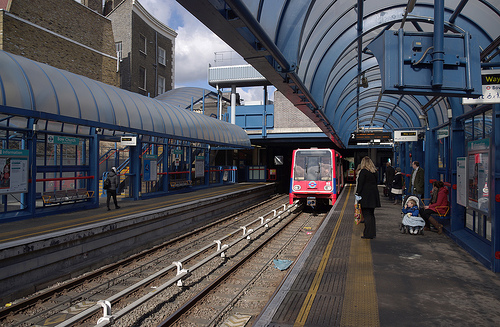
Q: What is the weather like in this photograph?
A: It is cloudy.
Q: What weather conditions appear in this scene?
A: It is cloudy.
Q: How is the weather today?
A: It is cloudy.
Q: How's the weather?
A: It is cloudy.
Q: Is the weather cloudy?
A: Yes, it is cloudy.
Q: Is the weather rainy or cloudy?
A: It is cloudy.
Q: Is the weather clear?
A: No, it is cloudy.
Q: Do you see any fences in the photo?
A: No, there are no fences.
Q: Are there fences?
A: No, there are no fences.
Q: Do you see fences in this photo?
A: No, there are no fences.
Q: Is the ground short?
A: Yes, the ground is short.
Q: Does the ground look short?
A: Yes, the ground is short.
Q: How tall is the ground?
A: The ground is short.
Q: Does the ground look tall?
A: No, the ground is short.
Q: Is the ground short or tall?
A: The ground is short.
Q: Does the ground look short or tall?
A: The ground is short.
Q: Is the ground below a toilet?
A: No, the ground is below the woman.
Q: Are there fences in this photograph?
A: No, there are no fences.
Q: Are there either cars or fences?
A: No, there are no fences or cars.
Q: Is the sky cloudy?
A: Yes, the sky is cloudy.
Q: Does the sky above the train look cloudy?
A: Yes, the sky is cloudy.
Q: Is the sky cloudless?
A: No, the sky is cloudy.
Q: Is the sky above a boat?
A: No, the sky is above a woman.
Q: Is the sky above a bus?
A: No, the sky is above the train.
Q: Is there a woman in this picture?
A: Yes, there is a woman.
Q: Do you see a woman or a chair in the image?
A: Yes, there is a woman.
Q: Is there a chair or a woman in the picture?
A: Yes, there is a woman.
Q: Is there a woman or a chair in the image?
A: Yes, there is a woman.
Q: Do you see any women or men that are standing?
A: Yes, the woman is standing.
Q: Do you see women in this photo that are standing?
A: Yes, there is a woman that is standing.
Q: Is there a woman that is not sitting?
A: Yes, there is a woman that is standing.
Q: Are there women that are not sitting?
A: Yes, there is a woman that is standing.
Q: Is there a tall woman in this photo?
A: Yes, there is a tall woman.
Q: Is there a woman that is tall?
A: Yes, there is a woman that is tall.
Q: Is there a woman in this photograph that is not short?
A: Yes, there is a tall woman.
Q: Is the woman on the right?
A: Yes, the woman is on the right of the image.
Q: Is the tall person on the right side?
A: Yes, the woman is on the right of the image.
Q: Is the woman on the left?
A: No, the woman is on the right of the image.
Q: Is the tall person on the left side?
A: No, the woman is on the right of the image.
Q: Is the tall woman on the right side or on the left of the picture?
A: The woman is on the right of the image.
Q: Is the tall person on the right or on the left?
A: The woman is on the right of the image.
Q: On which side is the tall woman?
A: The woman is on the right of the image.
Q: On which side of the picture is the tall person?
A: The woman is on the right of the image.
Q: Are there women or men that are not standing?
A: No, there is a woman but she is standing.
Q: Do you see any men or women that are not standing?
A: No, there is a woman but she is standing.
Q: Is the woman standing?
A: Yes, the woman is standing.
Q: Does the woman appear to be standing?
A: Yes, the woman is standing.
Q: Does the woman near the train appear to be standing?
A: Yes, the woman is standing.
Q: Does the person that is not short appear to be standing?
A: Yes, the woman is standing.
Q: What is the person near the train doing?
A: The woman is standing.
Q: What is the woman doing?
A: The woman is standing.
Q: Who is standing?
A: The woman is standing.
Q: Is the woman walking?
A: No, the woman is standing.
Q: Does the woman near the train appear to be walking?
A: No, the woman is standing.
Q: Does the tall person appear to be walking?
A: No, the woman is standing.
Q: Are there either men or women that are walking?
A: No, there is a woman but she is standing.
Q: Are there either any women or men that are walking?
A: No, there is a woman but she is standing.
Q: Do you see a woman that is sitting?
A: No, there is a woman but she is standing.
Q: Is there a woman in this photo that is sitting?
A: No, there is a woman but she is standing.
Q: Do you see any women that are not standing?
A: No, there is a woman but she is standing.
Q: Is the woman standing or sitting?
A: The woman is standing.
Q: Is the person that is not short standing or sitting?
A: The woman is standing.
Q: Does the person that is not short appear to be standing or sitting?
A: The woman is standing.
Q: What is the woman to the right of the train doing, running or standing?
A: The woman is standing.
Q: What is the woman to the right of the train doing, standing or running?
A: The woman is standing.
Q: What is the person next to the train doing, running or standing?
A: The woman is standing.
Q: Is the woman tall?
A: Yes, the woman is tall.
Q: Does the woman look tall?
A: Yes, the woman is tall.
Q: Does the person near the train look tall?
A: Yes, the woman is tall.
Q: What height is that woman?
A: The woman is tall.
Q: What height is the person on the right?
A: The woman is tall.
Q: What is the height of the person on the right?
A: The woman is tall.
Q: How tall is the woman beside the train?
A: The woman is tall.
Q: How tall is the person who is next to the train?
A: The woman is tall.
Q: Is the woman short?
A: No, the woman is tall.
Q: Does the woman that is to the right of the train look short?
A: No, the woman is tall.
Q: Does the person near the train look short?
A: No, the woman is tall.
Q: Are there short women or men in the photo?
A: No, there is a woman but she is tall.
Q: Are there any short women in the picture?
A: No, there is a woman but she is tall.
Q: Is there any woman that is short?
A: No, there is a woman but she is tall.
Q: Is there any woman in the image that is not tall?
A: No, there is a woman but she is tall.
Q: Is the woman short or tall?
A: The woman is tall.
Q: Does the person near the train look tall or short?
A: The woman is tall.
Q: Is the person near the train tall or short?
A: The woman is tall.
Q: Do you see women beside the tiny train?
A: Yes, there is a woman beside the train.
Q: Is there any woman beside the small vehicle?
A: Yes, there is a woman beside the train.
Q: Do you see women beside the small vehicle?
A: Yes, there is a woman beside the train.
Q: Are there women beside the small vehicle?
A: Yes, there is a woman beside the train.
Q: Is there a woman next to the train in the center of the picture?
A: Yes, there is a woman next to the train.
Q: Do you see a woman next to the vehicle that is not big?
A: Yes, there is a woman next to the train.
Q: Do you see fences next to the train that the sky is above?
A: No, there is a woman next to the train.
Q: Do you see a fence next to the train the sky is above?
A: No, there is a woman next to the train.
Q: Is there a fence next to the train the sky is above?
A: No, there is a woman next to the train.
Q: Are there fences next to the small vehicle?
A: No, there is a woman next to the train.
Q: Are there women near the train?
A: Yes, there is a woman near the train.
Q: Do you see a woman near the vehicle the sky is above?
A: Yes, there is a woman near the train.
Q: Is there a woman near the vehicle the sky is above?
A: Yes, there is a woman near the train.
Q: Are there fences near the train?
A: No, there is a woman near the train.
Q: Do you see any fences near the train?
A: No, there is a woman near the train.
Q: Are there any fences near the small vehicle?
A: No, there is a woman near the train.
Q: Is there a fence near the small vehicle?
A: No, there is a woman near the train.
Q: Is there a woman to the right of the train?
A: Yes, there is a woman to the right of the train.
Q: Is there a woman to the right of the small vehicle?
A: Yes, there is a woman to the right of the train.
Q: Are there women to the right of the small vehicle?
A: Yes, there is a woman to the right of the train.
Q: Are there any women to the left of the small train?
A: No, the woman is to the right of the train.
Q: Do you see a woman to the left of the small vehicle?
A: No, the woman is to the right of the train.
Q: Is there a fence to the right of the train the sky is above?
A: No, there is a woman to the right of the train.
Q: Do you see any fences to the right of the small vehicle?
A: No, there is a woman to the right of the train.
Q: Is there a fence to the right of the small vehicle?
A: No, there is a woman to the right of the train.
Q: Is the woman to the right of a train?
A: Yes, the woman is to the right of a train.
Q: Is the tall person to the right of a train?
A: Yes, the woman is to the right of a train.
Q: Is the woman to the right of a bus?
A: No, the woman is to the right of a train.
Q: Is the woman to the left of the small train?
A: No, the woman is to the right of the train.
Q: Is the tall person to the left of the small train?
A: No, the woman is to the right of the train.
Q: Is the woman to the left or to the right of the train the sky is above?
A: The woman is to the right of the train.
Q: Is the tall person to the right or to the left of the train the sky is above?
A: The woman is to the right of the train.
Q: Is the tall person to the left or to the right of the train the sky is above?
A: The woman is to the right of the train.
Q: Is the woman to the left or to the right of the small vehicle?
A: The woman is to the right of the train.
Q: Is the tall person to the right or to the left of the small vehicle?
A: The woman is to the right of the train.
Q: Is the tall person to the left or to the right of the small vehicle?
A: The woman is to the right of the train.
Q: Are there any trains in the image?
A: Yes, there is a train.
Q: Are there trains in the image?
A: Yes, there is a train.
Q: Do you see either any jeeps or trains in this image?
A: Yes, there is a train.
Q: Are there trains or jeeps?
A: Yes, there is a train.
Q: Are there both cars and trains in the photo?
A: No, there is a train but no cars.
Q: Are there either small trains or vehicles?
A: Yes, there is a small train.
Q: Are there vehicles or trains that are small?
A: Yes, the train is small.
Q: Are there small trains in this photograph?
A: Yes, there is a small train.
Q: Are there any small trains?
A: Yes, there is a small train.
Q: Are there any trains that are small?
A: Yes, there is a train that is small.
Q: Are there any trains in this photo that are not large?
A: Yes, there is a small train.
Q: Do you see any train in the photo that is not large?
A: Yes, there is a small train.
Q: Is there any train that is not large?
A: Yes, there is a small train.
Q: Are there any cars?
A: No, there are no cars.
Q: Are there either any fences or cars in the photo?
A: No, there are no cars or fences.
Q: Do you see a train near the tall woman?
A: Yes, there is a train near the woman.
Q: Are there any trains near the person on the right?
A: Yes, there is a train near the woman.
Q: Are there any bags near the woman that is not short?
A: No, there is a train near the woman.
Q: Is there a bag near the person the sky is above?
A: No, there is a train near the woman.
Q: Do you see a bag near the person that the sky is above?
A: No, there is a train near the woman.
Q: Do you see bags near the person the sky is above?
A: No, there is a train near the woman.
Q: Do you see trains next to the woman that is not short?
A: Yes, there is a train next to the woman.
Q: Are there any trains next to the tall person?
A: Yes, there is a train next to the woman.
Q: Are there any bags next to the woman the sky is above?
A: No, there is a train next to the woman.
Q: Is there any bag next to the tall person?
A: No, there is a train next to the woman.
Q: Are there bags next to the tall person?
A: No, there is a train next to the woman.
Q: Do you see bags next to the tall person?
A: No, there is a train next to the woman.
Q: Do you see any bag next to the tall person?
A: No, there is a train next to the woman.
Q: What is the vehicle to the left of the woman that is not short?
A: The vehicle is a train.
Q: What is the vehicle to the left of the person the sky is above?
A: The vehicle is a train.